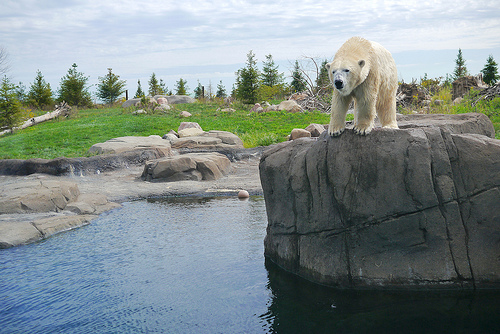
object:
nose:
[333, 80, 345, 90]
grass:
[0, 87, 498, 159]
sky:
[0, 0, 499, 99]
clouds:
[0, 0, 499, 106]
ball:
[234, 188, 250, 202]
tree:
[50, 63, 96, 110]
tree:
[96, 67, 127, 104]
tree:
[235, 50, 261, 105]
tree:
[260, 53, 287, 99]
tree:
[287, 57, 306, 99]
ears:
[322, 58, 331, 66]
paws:
[327, 124, 344, 137]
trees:
[0, 48, 34, 125]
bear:
[323, 36, 400, 136]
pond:
[0, 188, 499, 333]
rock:
[258, 111, 499, 291]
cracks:
[456, 199, 478, 284]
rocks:
[0, 174, 78, 217]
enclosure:
[0, 76, 498, 333]